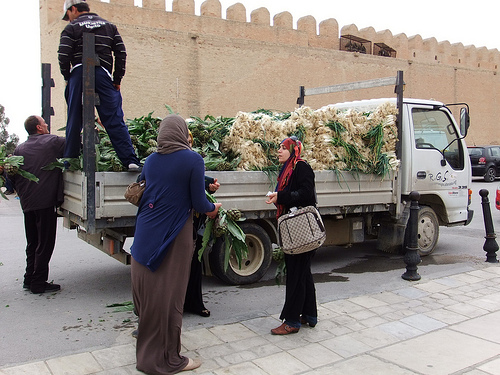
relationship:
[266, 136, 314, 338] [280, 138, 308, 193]
ladies wearing head scarf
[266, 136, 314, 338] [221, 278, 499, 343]
ladies in street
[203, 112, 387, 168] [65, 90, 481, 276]
plants in truck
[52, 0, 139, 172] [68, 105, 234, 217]
man in truck bed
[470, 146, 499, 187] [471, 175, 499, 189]
car in street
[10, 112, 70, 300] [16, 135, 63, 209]
man wearing jacket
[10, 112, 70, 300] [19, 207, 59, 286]
man wearing pants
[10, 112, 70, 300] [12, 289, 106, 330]
man on pavement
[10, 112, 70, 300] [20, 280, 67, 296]
man wearing shoes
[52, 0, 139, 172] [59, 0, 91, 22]
man wearing baseball cap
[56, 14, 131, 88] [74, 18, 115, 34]
jacket has lettering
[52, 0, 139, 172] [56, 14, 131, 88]
man wearing jacket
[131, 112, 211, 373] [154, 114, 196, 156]
lady wearing scarf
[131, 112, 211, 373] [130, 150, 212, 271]
woman wearing sweater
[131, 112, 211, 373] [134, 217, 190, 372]
woman wearing skirt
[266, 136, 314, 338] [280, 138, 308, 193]
ladies wearing scarf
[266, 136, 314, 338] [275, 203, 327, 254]
ladies carrying bag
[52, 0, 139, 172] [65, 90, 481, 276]
person on truck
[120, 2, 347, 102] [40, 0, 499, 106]
building in background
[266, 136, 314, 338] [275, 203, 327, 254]
ladies holding purse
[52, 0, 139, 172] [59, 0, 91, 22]
man wearing cap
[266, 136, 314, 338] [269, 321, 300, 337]
ladies wearing shoes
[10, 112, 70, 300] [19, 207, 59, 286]
man has pants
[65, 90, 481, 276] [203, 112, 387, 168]
truck carrying plants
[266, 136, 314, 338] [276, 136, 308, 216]
ladies with head scarf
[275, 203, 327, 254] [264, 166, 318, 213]
purse on arm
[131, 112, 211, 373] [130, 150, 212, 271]
lady wearing coat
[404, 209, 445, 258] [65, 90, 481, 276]
wheel of truck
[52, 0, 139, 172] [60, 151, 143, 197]
work clothes standing bed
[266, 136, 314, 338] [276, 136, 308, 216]
ladies wearing head scarf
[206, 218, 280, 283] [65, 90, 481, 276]
tire of truck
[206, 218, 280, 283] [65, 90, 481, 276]
wheels on truck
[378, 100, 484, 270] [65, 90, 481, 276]
front of truck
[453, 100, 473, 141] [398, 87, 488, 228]
mirror on side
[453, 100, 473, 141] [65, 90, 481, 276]
mirror on truck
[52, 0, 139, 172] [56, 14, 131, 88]
man wearing sweater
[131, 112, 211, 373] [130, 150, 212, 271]
lady wearing sweater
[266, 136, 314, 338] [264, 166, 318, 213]
ladies wearing jacket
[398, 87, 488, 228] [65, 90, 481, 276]
door of truck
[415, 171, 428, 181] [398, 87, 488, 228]
handle on door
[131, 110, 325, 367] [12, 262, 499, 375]
ladies on pavement